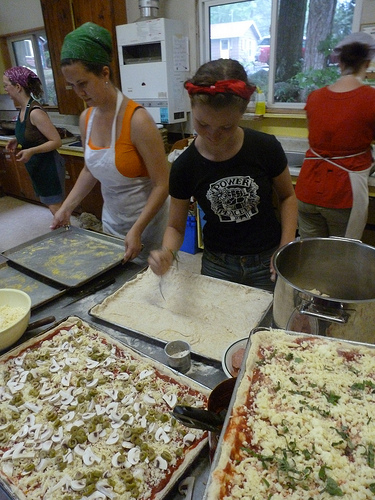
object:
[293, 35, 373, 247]
woman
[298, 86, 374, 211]
top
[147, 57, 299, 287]
girl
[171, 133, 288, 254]
t-shirt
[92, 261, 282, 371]
dough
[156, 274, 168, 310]
fork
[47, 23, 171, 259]
woman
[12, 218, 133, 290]
tray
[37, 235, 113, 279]
cornmeal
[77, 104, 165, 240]
apron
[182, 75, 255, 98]
headband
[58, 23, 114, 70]
scarf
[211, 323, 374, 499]
pizza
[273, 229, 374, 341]
pot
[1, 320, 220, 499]
pizza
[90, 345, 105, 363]
mushroom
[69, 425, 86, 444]
mushroom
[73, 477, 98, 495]
mushroom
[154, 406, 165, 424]
mushroom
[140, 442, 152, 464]
mushroom